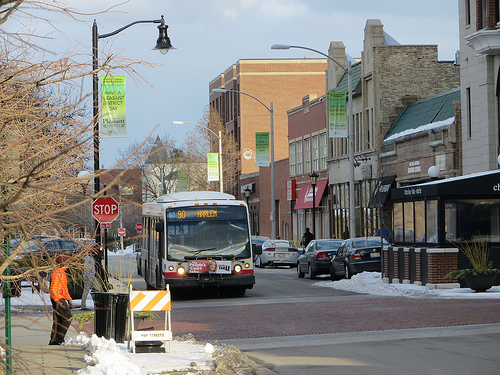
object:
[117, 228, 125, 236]
stop sign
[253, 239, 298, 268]
car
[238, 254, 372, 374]
street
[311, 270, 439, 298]
snow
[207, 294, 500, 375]
ground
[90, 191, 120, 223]
stop sign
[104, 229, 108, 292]
pole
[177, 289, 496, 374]
road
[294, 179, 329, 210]
awning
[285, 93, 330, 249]
building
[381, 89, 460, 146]
roof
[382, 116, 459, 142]
snow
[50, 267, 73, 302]
jacket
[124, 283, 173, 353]
barrier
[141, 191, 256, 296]
bus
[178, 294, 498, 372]
street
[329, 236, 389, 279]
car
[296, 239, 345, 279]
car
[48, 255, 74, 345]
person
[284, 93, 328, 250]
store front